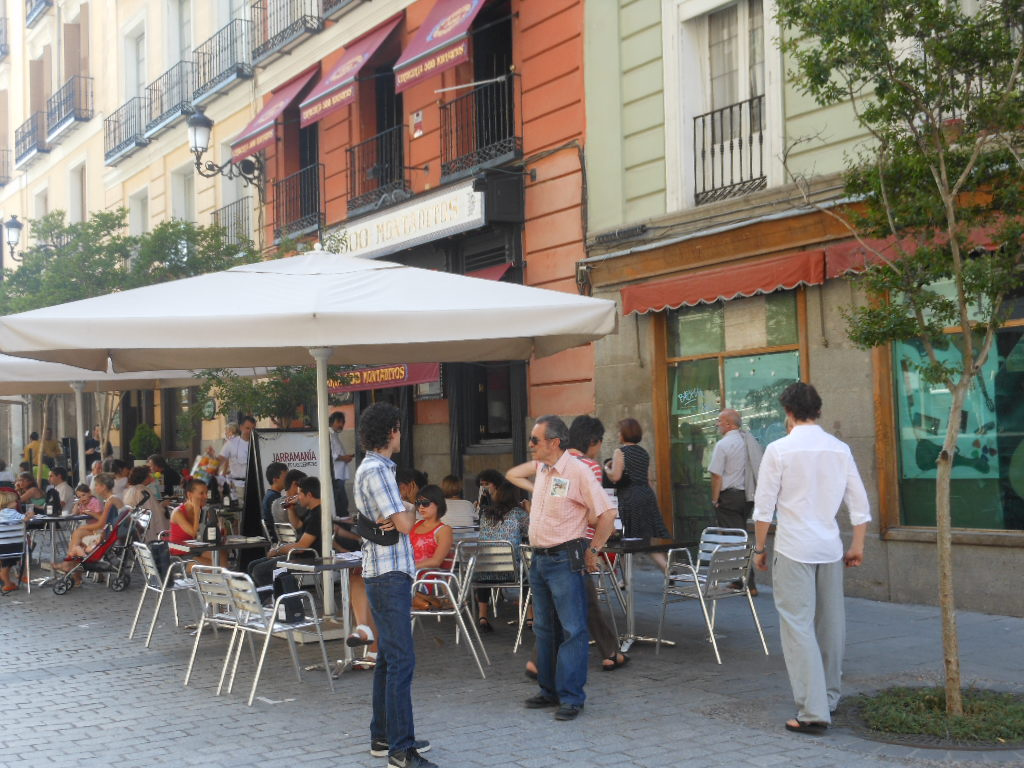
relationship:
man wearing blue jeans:
[522, 415, 620, 724] [528, 538, 589, 703]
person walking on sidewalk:
[704, 400, 769, 535] [596, 557, 1022, 689]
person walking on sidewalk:
[600, 417, 674, 591] [596, 557, 1022, 689]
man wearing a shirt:
[742, 372, 864, 735] [746, 424, 876, 567]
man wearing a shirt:
[350, 405, 441, 767] [348, 456, 426, 590]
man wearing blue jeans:
[350, 405, 441, 767] [359, 547, 435, 753]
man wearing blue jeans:
[350, 405, 441, 767] [361, 543, 426, 758]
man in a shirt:
[522, 415, 620, 724] [523, 456, 612, 550]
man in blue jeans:
[522, 415, 620, 724] [521, 536, 602, 703]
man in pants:
[751, 380, 871, 734] [765, 539, 848, 721]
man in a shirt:
[751, 380, 871, 734] [746, 424, 876, 567]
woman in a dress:
[350, 482, 450, 666] [413, 523, 444, 554]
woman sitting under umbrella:
[350, 482, 450, 666] [27, 242, 626, 670]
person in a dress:
[600, 417, 674, 591] [612, 443, 662, 541]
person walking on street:
[600, 417, 674, 591] [463, 510, 885, 670]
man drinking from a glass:
[279, 480, 321, 556] [292, 495, 306, 511]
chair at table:
[672, 502, 765, 656] [608, 523, 667, 658]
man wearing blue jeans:
[350, 405, 441, 767] [362, 571, 414, 759]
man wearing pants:
[751, 380, 871, 734] [770, 550, 850, 723]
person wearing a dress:
[600, 417, 674, 591] [619, 450, 665, 541]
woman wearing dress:
[345, 483, 454, 674] [410, 520, 449, 594]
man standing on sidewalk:
[350, 405, 441, 767] [320, 726, 567, 763]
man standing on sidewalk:
[709, 396, 762, 595] [673, 558, 771, 611]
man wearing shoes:
[525, 415, 616, 722] [526, 679, 598, 734]